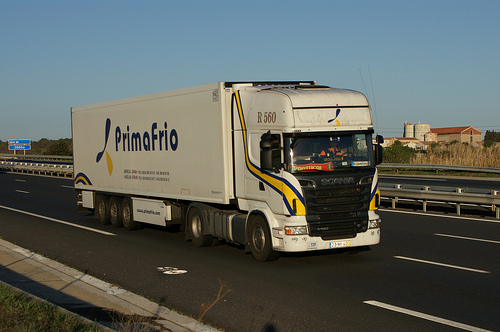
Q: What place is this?
A: It is a road.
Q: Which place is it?
A: It is a road.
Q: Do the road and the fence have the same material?
A: No, the road is made of concrete and the fence is made of metal.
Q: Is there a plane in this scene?
A: No, there are no airplanes.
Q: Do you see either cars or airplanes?
A: No, there are no airplanes or cars.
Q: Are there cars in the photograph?
A: No, there are no cars.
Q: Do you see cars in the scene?
A: No, there are no cars.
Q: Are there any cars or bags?
A: No, there are no cars or bags.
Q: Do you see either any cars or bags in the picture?
A: No, there are no cars or bags.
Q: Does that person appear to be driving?
A: Yes, the person is driving.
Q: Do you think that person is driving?
A: Yes, the person is driving.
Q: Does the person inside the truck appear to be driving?
A: Yes, the person is driving.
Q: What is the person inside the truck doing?
A: The person is driving.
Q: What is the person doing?
A: The person is driving.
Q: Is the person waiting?
A: No, the person is driving.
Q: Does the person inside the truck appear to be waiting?
A: No, the person is driving.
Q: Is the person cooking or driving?
A: The person is driving.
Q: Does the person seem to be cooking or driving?
A: The person is driving.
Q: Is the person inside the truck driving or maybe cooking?
A: The person is driving.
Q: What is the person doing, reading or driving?
A: The person is driving.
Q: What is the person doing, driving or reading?
A: The person is driving.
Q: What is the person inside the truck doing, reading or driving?
A: The person is driving.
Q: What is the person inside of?
A: The person is inside the truck.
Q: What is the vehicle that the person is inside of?
A: The vehicle is a truck.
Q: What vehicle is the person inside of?
A: The person is inside the truck.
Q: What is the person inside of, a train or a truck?
A: The person is inside a truck.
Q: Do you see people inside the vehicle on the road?
A: Yes, there is a person inside the truck.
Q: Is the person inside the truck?
A: Yes, the person is inside the truck.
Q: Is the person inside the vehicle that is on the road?
A: Yes, the person is inside the truck.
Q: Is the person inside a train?
A: No, the person is inside the truck.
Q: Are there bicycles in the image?
A: No, there are no bicycles.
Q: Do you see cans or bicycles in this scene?
A: No, there are no bicycles or cans.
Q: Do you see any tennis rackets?
A: No, there are no tennis rackets.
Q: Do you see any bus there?
A: No, there are no buses.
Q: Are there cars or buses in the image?
A: No, there are no buses or cars.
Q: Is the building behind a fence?
A: Yes, the building is behind a fence.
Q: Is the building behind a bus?
A: No, the building is behind a fence.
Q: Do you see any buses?
A: No, there are no buses.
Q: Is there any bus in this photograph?
A: No, there are no buses.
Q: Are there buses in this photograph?
A: No, there are no buses.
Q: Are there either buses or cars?
A: No, there are no buses or cars.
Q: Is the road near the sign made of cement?
A: Yes, the road is made of cement.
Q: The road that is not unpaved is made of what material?
A: The road is made of concrete.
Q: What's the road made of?
A: The road is made of concrete.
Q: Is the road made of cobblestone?
A: No, the road is made of cement.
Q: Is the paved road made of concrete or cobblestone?
A: The road is made of concrete.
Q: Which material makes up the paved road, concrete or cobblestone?
A: The road is made of concrete.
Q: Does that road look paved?
A: Yes, the road is paved.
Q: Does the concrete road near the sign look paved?
A: Yes, the road is paved.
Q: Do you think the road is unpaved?
A: No, the road is paved.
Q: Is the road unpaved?
A: No, the road is paved.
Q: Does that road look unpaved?
A: No, the road is paved.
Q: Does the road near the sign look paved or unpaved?
A: The road is paved.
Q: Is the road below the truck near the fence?
A: Yes, the road is below the truck.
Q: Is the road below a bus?
A: No, the road is below the truck.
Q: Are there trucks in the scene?
A: Yes, there is a truck.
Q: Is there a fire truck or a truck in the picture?
A: Yes, there is a truck.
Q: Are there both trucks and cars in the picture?
A: No, there is a truck but no cars.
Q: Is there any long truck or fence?
A: Yes, there is a long truck.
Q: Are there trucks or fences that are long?
A: Yes, the truck is long.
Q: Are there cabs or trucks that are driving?
A: Yes, the truck is driving.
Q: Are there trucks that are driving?
A: Yes, there is a truck that is driving.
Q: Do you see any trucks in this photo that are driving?
A: Yes, there is a truck that is driving.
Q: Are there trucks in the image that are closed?
A: Yes, there is a closed truck.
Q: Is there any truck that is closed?
A: Yes, there is a truck that is closed.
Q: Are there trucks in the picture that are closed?
A: Yes, there is a truck that is closed.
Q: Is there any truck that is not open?
A: Yes, there is an closed truck.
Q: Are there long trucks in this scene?
A: Yes, there is a long truck.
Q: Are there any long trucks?
A: Yes, there is a long truck.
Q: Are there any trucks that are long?
A: Yes, there is a truck that is long.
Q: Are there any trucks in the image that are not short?
A: Yes, there is a long truck.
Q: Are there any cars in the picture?
A: No, there are no cars.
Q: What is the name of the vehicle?
A: The vehicle is a truck.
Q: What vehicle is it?
A: The vehicle is a truck.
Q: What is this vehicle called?
A: This is a truck.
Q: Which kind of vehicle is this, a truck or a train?
A: This is a truck.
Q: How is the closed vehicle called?
A: The vehicle is a truck.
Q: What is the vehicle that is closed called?
A: The vehicle is a truck.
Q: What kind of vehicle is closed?
A: The vehicle is a truck.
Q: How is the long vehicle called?
A: The vehicle is a truck.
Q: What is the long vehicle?
A: The vehicle is a truck.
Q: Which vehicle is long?
A: The vehicle is a truck.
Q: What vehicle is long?
A: The vehicle is a truck.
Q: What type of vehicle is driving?
A: The vehicle is a truck.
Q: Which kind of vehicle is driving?
A: The vehicle is a truck.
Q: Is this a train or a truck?
A: This is a truck.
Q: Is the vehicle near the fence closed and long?
A: Yes, the truck is closed and long.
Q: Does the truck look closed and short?
A: No, the truck is closed but long.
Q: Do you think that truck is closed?
A: Yes, the truck is closed.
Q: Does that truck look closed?
A: Yes, the truck is closed.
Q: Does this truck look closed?
A: Yes, the truck is closed.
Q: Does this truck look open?
A: No, the truck is closed.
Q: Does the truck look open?
A: No, the truck is closed.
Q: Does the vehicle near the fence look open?
A: No, the truck is closed.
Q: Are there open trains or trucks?
A: No, there is a truck but it is closed.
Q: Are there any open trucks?
A: No, there is a truck but it is closed.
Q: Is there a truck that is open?
A: No, there is a truck but it is closed.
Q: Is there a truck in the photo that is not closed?
A: No, there is a truck but it is closed.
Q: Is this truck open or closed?
A: The truck is closed.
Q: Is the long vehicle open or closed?
A: The truck is closed.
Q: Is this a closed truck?
A: Yes, this is a closed truck.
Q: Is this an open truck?
A: No, this is a closed truck.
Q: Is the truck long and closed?
A: Yes, the truck is long and closed.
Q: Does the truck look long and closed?
A: Yes, the truck is long and closed.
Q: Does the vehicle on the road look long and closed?
A: Yes, the truck is long and closed.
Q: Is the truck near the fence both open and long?
A: No, the truck is long but closed.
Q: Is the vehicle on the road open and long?
A: No, the truck is long but closed.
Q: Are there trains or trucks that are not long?
A: No, there is a truck but it is long.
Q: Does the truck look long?
A: Yes, the truck is long.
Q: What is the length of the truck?
A: The truck is long.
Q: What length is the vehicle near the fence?
A: The truck is long.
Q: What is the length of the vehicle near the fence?
A: The truck is long.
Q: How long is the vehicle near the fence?
A: The truck is long.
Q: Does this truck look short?
A: No, the truck is long.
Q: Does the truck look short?
A: No, the truck is long.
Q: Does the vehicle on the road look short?
A: No, the truck is long.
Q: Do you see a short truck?
A: No, there is a truck but it is long.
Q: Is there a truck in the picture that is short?
A: No, there is a truck but it is long.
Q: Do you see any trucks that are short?
A: No, there is a truck but it is long.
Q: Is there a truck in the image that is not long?
A: No, there is a truck but it is long.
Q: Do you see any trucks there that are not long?
A: No, there is a truck but it is long.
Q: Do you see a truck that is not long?
A: No, there is a truck but it is long.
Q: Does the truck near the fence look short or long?
A: The truck is long.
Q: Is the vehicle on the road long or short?
A: The truck is long.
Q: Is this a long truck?
A: Yes, this is a long truck.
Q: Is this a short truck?
A: No, this is a long truck.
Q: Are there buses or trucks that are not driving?
A: No, there is a truck but it is driving.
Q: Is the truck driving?
A: Yes, the truck is driving.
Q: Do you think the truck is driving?
A: Yes, the truck is driving.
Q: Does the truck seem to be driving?
A: Yes, the truck is driving.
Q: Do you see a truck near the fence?
A: Yes, there is a truck near the fence.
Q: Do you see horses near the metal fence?
A: No, there is a truck near the fence.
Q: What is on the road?
A: The truck is on the road.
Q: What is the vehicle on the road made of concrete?
A: The vehicle is a truck.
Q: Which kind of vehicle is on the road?
A: The vehicle is a truck.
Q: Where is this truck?
A: The truck is on the road.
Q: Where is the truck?
A: The truck is on the road.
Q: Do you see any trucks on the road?
A: Yes, there is a truck on the road.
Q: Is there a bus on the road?
A: No, there is a truck on the road.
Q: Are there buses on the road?
A: No, there is a truck on the road.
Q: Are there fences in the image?
A: Yes, there is a fence.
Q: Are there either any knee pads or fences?
A: Yes, there is a fence.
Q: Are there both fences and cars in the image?
A: No, there is a fence but no cars.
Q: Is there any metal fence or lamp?
A: Yes, there is a metal fence.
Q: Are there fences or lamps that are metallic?
A: Yes, the fence is metallic.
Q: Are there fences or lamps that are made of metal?
A: Yes, the fence is made of metal.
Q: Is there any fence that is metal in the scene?
A: Yes, there is a metal fence.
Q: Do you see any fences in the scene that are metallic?
A: Yes, there is a fence that is metallic.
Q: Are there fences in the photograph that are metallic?
A: Yes, there is a fence that is metallic.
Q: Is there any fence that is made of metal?
A: Yes, there is a fence that is made of metal.